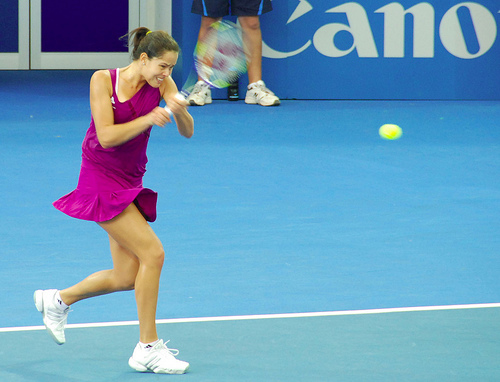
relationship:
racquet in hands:
[184, 21, 263, 105] [151, 95, 184, 125]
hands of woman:
[151, 95, 184, 125] [29, 21, 205, 381]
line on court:
[5, 286, 499, 341] [8, 104, 499, 381]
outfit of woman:
[48, 66, 174, 218] [29, 21, 205, 381]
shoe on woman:
[133, 338, 192, 376] [29, 21, 205, 381]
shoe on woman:
[31, 287, 72, 348] [29, 21, 205, 381]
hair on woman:
[127, 26, 177, 59] [29, 21, 205, 381]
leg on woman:
[92, 204, 187, 367] [29, 21, 205, 381]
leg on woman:
[49, 218, 146, 320] [29, 21, 205, 381]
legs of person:
[189, 17, 266, 87] [186, 4, 281, 113]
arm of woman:
[88, 75, 170, 147] [29, 21, 205, 381]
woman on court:
[29, 21, 205, 381] [8, 104, 499, 381]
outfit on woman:
[48, 66, 174, 218] [29, 21, 205, 381]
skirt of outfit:
[47, 163, 162, 230] [48, 66, 174, 218]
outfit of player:
[48, 66, 174, 218] [29, 21, 205, 381]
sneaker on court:
[133, 338, 192, 376] [8, 104, 499, 381]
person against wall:
[186, 4, 281, 113] [149, 2, 493, 105]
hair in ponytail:
[127, 26, 177, 59] [127, 26, 149, 50]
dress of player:
[48, 66, 174, 218] [29, 21, 205, 381]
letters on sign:
[314, 3, 497, 68] [149, 2, 493, 105]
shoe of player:
[133, 338, 192, 376] [29, 21, 205, 381]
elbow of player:
[88, 131, 119, 151] [29, 21, 205, 381]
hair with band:
[127, 26, 177, 59] [142, 30, 152, 36]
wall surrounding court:
[149, 2, 493, 105] [8, 104, 499, 381]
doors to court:
[4, 2, 146, 77] [8, 104, 499, 381]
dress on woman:
[48, 66, 174, 218] [29, 21, 205, 381]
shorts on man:
[191, 0, 276, 19] [186, 4, 281, 113]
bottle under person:
[225, 68, 242, 101] [186, 4, 281, 113]